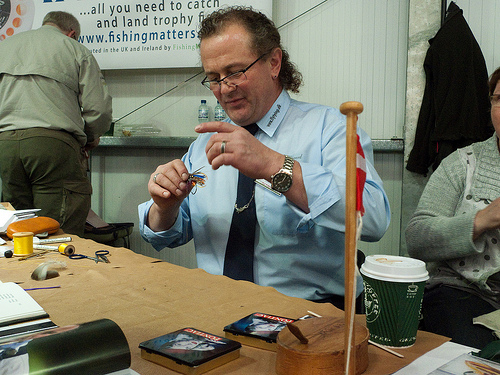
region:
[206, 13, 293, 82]
man has curly hair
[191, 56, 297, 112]
man is wearing glasses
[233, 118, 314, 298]
man has black tie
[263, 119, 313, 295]
man has blue shirt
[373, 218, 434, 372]
coffee cup on table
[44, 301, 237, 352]
table is light brown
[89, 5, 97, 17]
black letter on sign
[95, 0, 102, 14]
black letter on sign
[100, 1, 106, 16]
black letter on sign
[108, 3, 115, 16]
black letter on sign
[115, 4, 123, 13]
black letter on sign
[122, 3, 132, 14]
black letter on sign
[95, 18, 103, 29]
black letter on sign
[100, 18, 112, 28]
black letter on sign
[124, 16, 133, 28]
black letter on sign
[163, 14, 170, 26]
black letter on sign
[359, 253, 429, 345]
green paper cup with a white lid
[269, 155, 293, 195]
large silver watch with a black face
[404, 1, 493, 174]
black jacket hanging on the wall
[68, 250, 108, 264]
small pair of blue handled scissors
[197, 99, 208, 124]
plastic blue water bottle with blue lid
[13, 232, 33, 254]
spool of yellow thread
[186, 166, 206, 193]
fly the man is tying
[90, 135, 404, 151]
narrow shelf on the back wall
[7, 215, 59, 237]
small orange storage case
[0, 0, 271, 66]
white sign on the wall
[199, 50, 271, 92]
glasses with black rims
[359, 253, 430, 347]
green colored starbucks cup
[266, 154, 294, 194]
silver watch on man's wrist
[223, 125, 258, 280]
dark colored tie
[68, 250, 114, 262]
pair of scissors with dark colored handles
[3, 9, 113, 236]
man in a green shirt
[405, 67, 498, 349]
woman sitting down in a chair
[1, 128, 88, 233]
pair of green men's pants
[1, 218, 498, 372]
brown colored table with stuff on it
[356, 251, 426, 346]
A cup of coffee with a lid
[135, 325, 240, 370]
A metal box for holding fishing flies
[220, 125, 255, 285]
navy blue tie on man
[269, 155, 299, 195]
wristwatch on man's left arm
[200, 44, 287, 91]
eyeglasses on man's face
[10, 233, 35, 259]
large yellow spool of thread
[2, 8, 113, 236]
man standing at counter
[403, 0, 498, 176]
black jacket hanging on the wall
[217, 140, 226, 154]
ring on man's left hand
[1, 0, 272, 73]
sign hanging on the wall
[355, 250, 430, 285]
White lid on a cup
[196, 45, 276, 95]
A pair of eyeglasses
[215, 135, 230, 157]
A ring around a finger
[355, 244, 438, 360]
a green and white togo cup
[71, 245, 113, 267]
a small pair of black handled scissors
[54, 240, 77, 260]
a spool of yellow thread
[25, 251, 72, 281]
a simple feather on the counter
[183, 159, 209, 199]
a fly fishing fly being tied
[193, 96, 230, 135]
a pair of plastic water bottles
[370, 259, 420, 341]
cup on the table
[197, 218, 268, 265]
tie on the man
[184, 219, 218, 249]
the shirt is blue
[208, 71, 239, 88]
glasses on the man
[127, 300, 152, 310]
the table is wood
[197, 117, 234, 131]
finger on the hand